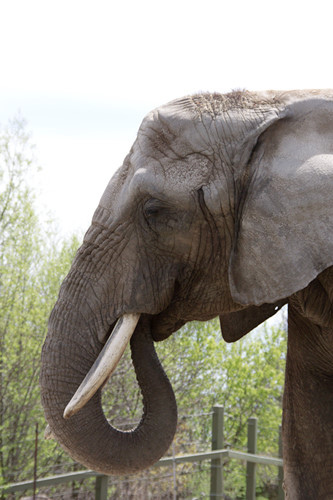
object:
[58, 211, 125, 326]
skin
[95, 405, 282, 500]
post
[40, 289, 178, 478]
trunk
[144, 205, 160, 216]
eye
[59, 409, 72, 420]
tip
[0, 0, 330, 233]
sky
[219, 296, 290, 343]
ear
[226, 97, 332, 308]
ear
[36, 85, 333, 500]
elephant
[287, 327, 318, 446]
part body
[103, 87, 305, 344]
elephant head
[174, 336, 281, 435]
trees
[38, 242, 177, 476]
curled trunk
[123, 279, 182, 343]
mouth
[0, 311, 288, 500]
gate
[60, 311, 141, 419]
tusk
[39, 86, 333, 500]
body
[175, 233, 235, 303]
skin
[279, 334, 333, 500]
leg